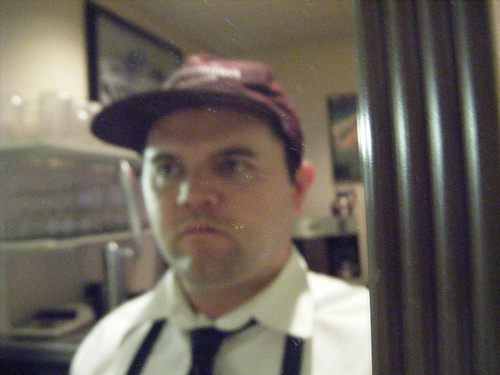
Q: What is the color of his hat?
A: Maroon.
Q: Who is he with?
A: No one.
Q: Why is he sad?
A: He is alone.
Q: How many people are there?
A: 1.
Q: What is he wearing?
A: A tie.